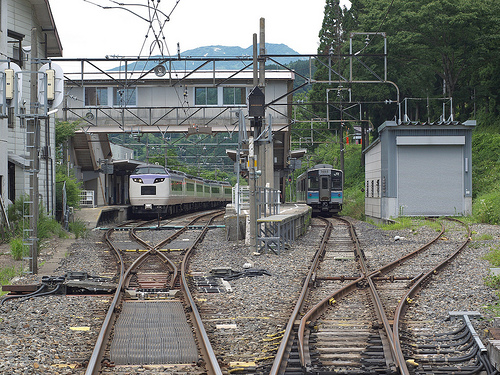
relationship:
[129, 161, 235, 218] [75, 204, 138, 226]
train stopped at platform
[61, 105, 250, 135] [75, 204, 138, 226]
bridge over platform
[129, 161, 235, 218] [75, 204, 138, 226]
train leaving platform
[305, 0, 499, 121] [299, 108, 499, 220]
trees on embankment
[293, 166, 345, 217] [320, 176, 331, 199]
train has rear door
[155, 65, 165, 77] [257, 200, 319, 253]
signal light to left of platform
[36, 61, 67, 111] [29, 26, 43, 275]
signal light on pole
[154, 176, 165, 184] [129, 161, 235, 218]
light on front of train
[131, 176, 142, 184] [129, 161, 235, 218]
light on front of train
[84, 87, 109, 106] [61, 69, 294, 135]
window on bridge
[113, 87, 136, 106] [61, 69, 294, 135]
window on bridge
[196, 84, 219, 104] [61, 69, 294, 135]
window on bridge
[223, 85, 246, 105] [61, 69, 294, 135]
window on bridge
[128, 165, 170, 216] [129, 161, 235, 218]
front of train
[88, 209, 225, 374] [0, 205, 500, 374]
railroad tracks on ground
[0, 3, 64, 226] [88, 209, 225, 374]
building next to railroad tracks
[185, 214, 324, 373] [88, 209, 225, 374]
gravel between railroad tracks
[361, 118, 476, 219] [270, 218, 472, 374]
shed next to train tracks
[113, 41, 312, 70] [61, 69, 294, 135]
mountain behind bridge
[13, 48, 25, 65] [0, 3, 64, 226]
window on building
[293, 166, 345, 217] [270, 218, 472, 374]
train on train tracks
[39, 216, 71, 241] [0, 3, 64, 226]
grass beside building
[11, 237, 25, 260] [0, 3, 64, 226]
grass beside building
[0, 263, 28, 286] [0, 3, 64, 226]
grass beside building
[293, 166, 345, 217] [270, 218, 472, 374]
train riding on train tracks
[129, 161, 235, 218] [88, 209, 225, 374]
train riding on railroad tracks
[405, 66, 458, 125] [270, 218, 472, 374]
antennas by train tracks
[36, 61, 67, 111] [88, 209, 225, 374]
signal light near railroad tracks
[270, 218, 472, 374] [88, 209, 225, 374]
train tracks intersect with railroad tracks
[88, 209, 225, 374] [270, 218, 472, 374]
railroad tracks intersect with train tracks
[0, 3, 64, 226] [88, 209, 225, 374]
building to left of railroad tracks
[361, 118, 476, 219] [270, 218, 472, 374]
shed at end of train tracks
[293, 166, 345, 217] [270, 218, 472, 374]
train on top of train tracks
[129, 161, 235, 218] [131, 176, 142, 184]
train has light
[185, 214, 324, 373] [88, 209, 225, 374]
gravel surrounding railroad tracks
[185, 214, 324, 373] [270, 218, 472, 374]
gravel surrounding train tracks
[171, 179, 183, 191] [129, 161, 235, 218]
window on outside of train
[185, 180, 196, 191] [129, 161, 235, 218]
window on outside of train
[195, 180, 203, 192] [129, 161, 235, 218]
window on outside of train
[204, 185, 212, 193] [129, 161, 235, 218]
window on outside of train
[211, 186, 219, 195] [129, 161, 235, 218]
window on outside of train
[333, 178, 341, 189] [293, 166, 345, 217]
window on train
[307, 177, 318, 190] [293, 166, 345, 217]
window on train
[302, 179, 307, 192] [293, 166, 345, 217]
window on train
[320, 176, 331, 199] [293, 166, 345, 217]
rear door on back of train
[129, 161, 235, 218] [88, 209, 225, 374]
train on top of railroad tracks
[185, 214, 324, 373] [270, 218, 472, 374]
gravel near train tracks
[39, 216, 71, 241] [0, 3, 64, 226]
grass near building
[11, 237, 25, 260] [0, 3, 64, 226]
grass near building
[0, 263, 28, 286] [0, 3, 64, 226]
grass near building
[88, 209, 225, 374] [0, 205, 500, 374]
railroad tracks on top of ground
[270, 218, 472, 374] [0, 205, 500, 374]
train tracks on top of ground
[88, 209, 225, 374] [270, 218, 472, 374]
railroad tracks next to train tracks